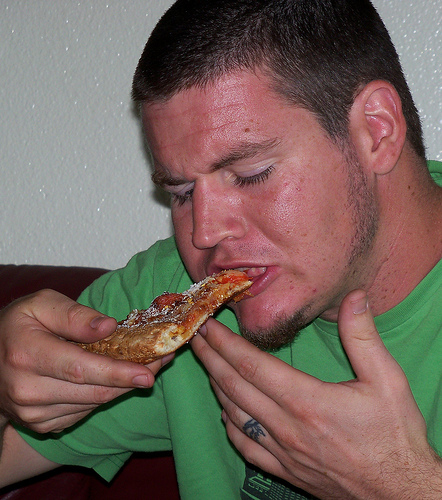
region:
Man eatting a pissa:
[56, 10, 410, 492]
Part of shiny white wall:
[38, 236, 79, 265]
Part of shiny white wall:
[89, 235, 125, 265]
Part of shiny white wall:
[118, 177, 154, 231]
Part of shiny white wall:
[72, 165, 113, 224]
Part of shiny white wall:
[14, 160, 55, 206]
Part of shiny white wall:
[24, 83, 54, 168]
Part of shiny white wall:
[57, 69, 121, 161]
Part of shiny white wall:
[400, 20, 441, 133]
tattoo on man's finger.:
[240, 413, 267, 443]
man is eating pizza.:
[86, 256, 276, 363]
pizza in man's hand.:
[18, 288, 177, 392]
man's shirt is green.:
[0, 222, 440, 498]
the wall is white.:
[0, 1, 186, 275]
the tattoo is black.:
[238, 412, 264, 446]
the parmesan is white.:
[114, 272, 213, 326]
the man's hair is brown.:
[125, 0, 424, 155]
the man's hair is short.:
[114, 2, 424, 166]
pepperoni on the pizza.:
[147, 291, 186, 308]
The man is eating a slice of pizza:
[33, 3, 439, 371]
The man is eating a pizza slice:
[41, 10, 411, 360]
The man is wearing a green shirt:
[70, 265, 438, 488]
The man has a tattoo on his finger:
[232, 406, 276, 445]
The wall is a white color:
[15, 12, 122, 232]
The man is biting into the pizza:
[78, 239, 295, 376]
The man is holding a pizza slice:
[3, 238, 250, 429]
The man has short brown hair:
[114, 7, 428, 162]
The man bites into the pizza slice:
[77, 250, 280, 366]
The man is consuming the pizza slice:
[59, 236, 295, 383]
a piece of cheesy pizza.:
[74, 261, 270, 380]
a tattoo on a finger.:
[233, 412, 278, 451]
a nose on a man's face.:
[187, 159, 249, 260]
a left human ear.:
[339, 79, 414, 193]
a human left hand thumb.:
[336, 286, 414, 381]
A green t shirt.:
[13, 235, 440, 497]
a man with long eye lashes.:
[195, 130, 289, 201]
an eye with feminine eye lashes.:
[155, 166, 211, 220]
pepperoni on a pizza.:
[137, 282, 181, 332]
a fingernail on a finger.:
[195, 315, 215, 347]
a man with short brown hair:
[134, 4, 425, 352]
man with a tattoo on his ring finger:
[240, 415, 265, 444]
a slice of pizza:
[72, 269, 250, 364]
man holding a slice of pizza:
[1, 259, 251, 438]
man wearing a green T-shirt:
[9, 161, 441, 497]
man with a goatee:
[232, 310, 306, 352]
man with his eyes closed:
[158, 150, 276, 207]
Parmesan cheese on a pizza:
[114, 271, 212, 329]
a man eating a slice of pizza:
[1, 0, 438, 495]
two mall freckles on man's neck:
[407, 182, 415, 198]